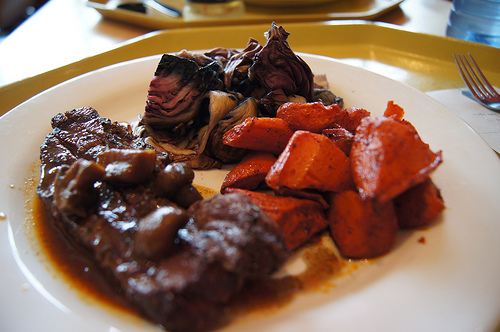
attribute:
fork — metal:
[448, 40, 498, 110]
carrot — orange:
[352, 118, 434, 202]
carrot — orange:
[333, 176, 410, 257]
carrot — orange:
[257, 131, 354, 191]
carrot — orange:
[217, 111, 292, 153]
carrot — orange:
[226, 176, 328, 246]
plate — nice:
[401, 63, 487, 163]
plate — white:
[449, 179, 491, 315]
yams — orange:
[255, 94, 431, 242]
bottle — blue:
[436, 0, 497, 43]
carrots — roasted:
[226, 99, 443, 256]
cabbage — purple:
[137, 13, 307, 122]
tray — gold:
[0, 20, 485, 119]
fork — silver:
[453, 50, 484, 110]